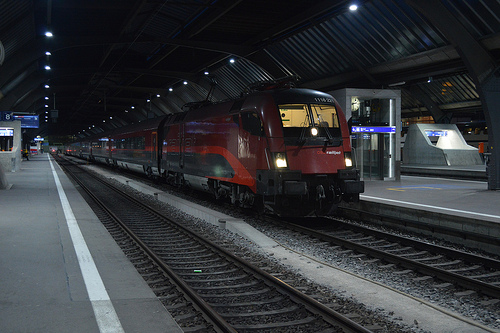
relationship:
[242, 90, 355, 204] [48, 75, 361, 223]
cabin of train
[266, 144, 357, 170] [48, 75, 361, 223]
headlights of train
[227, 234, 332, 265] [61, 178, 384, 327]
gravel between tracks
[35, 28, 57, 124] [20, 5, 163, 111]
lights are on roof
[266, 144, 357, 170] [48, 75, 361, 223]
headlights are on train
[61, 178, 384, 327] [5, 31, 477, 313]
tracks are in station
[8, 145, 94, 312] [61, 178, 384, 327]
walkway beside tracks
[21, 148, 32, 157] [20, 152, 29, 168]
man sits on chair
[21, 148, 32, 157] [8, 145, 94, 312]
man on walkway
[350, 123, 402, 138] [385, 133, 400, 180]
sign on pole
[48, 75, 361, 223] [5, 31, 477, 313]
train in station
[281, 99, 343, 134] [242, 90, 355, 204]
windows on cabin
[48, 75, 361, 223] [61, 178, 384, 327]
train on tracks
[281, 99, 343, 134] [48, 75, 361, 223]
windshield on train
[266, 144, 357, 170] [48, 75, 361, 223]
headlights on train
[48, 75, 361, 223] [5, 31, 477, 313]
train passing through station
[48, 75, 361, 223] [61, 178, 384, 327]
train rolls on tracks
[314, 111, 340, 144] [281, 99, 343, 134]
wipers on windows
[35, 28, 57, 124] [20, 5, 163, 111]
lights on roof